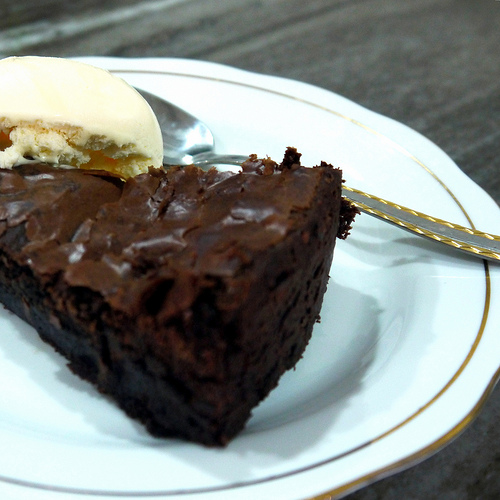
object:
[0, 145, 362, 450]
cake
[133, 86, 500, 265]
spoon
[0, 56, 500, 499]
plate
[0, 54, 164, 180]
ice cream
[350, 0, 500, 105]
table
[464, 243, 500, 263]
gold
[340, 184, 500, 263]
detail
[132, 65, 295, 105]
detail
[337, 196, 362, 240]
crumb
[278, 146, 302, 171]
crumb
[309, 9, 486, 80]
part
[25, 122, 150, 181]
sauce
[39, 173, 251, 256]
crust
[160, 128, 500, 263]
handle